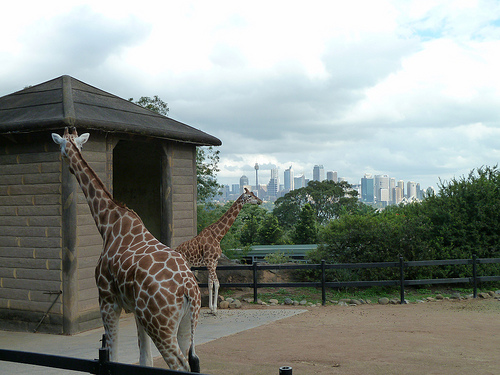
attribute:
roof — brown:
[2, 76, 226, 146]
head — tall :
[54, 150, 123, 216]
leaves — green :
[326, 216, 431, 286]